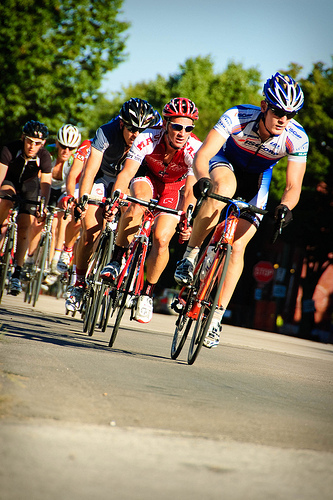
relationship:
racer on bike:
[173, 72, 309, 347] [170, 180, 288, 364]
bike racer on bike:
[112, 96, 203, 324] [106, 184, 178, 354]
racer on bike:
[66, 95, 152, 308] [0, 183, 34, 311]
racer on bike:
[0, 113, 50, 285] [69, 186, 108, 318]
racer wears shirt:
[84, 95, 207, 300] [129, 129, 199, 191]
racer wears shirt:
[173, 72, 309, 347] [213, 103, 309, 174]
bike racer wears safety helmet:
[28, 124, 90, 302] [57, 116, 79, 153]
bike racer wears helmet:
[137, 84, 203, 229] [161, 92, 199, 121]